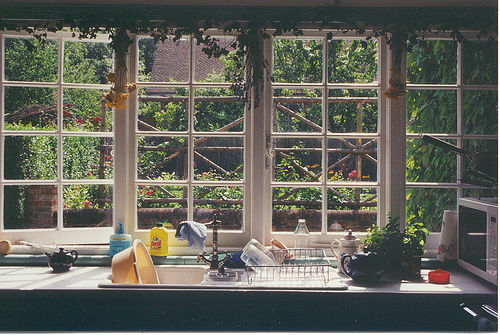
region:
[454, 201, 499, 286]
a white microwave oven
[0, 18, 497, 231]
windows with a view of a garden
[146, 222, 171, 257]
a yellow bottle of dish soap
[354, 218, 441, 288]
plants growing on the counter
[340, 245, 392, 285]
a teapot on the counter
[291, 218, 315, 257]
a clear bottle beside a window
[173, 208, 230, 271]
a metal sink faucet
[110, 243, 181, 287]
a bowl in a sink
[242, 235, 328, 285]
dished drying on a rack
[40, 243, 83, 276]
a small tea pot on a counter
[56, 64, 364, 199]
view is in the kitchen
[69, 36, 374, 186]
plants are seen through the window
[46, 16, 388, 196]
plants are green in color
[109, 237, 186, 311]
the bain is in the sink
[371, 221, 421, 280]
the plant is besid the window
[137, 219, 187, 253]
the container is yellow in color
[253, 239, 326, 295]
the tray has some white bottles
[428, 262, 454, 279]
the tin is red in ocolor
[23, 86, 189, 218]
window panes are white in color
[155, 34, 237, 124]
a house roof is seen through the window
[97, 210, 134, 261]
hand soap with pump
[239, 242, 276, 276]
glass jar in dish rack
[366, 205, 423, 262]
plant on the counter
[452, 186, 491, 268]
white microwave on the counter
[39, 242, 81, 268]
small brown teapot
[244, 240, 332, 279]
white dish rack on sink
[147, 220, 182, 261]
cleaner in yellow bottle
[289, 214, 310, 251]
glass jar on the counter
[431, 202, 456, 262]
paper towel by microwave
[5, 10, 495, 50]
plants hanging above window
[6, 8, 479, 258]
the window is white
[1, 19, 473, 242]
plants behind a window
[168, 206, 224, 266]
a towel on top a faucet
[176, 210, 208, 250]
towel is color blue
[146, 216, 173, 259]
a bottle is yellow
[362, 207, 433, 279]
a pot with a plant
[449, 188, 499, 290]
the microwave is white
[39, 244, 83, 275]
a kettle on a counter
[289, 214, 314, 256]
an empty bottle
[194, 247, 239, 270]
handles of sink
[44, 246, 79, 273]
Small black teapot on counter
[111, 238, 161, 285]
Plastic yellow tub in sink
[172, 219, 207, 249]
Dish cloth hanging on faucet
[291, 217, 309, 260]
Clear glass bottle near window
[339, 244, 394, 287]
Dark colored tea pot on counter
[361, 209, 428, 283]
Green houseplant on counter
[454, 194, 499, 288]
White microwave oven on counter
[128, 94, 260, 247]
Paned glass window above sink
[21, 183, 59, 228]
Brick pillar outside of window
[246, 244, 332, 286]
White plastic dish drying rack